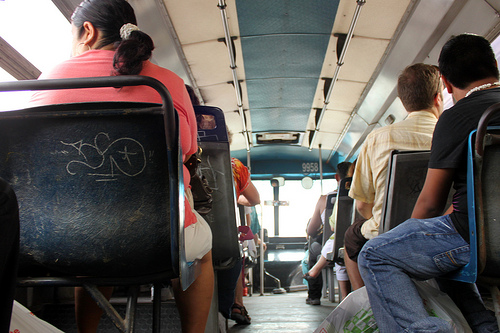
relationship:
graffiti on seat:
[55, 133, 157, 185] [1, 77, 200, 330]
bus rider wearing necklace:
[356, 33, 499, 332] [462, 78, 497, 105]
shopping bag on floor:
[311, 283, 381, 330] [217, 284, 343, 331]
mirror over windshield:
[267, 175, 284, 188] [258, 173, 318, 243]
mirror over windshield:
[298, 176, 315, 188] [258, 173, 318, 243]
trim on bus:
[229, 146, 339, 173] [3, 0, 489, 331]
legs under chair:
[88, 282, 143, 326] [0, 74, 203, 332]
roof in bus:
[176, 4, 375, 139] [3, 0, 489, 331]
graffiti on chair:
[50, 132, 148, 182] [4, 109, 182, 290]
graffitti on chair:
[197, 153, 227, 200] [4, 109, 182, 290]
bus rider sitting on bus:
[25, 0, 215, 332] [3, 0, 489, 331]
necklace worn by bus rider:
[462, 78, 497, 105] [25, 0, 215, 332]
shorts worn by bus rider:
[185, 205, 215, 262] [356, 30, 496, 331]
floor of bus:
[217, 288, 343, 332] [3, 0, 489, 331]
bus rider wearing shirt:
[25, 0, 215, 332] [15, 51, 203, 230]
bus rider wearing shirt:
[342, 63, 446, 291] [349, 109, 446, 224]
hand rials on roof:
[306, 2, 364, 152] [154, 0, 420, 150]